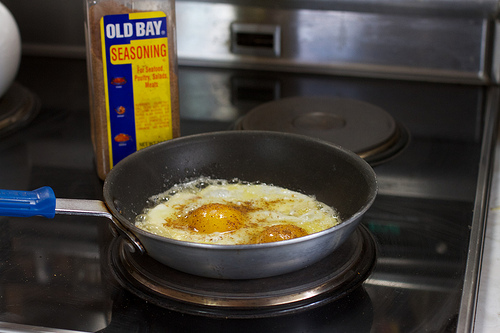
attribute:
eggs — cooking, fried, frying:
[133, 181, 338, 247]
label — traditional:
[99, 11, 170, 175]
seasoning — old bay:
[82, 0, 180, 181]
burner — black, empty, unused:
[237, 93, 410, 166]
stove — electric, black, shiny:
[0, 54, 499, 333]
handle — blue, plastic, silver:
[0, 184, 106, 217]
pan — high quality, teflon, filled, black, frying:
[102, 129, 376, 280]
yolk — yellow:
[192, 202, 236, 235]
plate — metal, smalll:
[115, 269, 361, 303]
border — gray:
[459, 81, 499, 333]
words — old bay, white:
[104, 20, 167, 89]